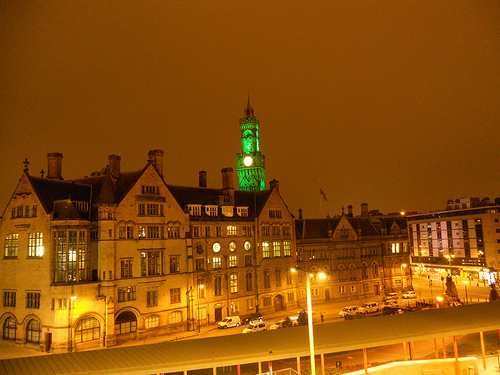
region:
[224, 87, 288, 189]
a clock tower lit up in green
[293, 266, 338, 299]
a street light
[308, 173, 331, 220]
a flag pole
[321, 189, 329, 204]
a flag hanging from the flag pole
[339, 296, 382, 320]
cars parked on the street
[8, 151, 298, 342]
a large building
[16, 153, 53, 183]
sculptures on top of the building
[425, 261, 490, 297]
traffic lights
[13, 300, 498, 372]
The roof of a covered walk way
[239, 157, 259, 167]
the clock on the clock tower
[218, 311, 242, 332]
a white van parked in front of a building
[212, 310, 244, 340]
a white van parked on side of raodway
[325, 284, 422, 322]
several vehicles parked on side of road way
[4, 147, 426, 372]
a large building with several windows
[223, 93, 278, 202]
a steeple on a building lit up in green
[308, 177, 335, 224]
a tall flag pole and flag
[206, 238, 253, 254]
three round windows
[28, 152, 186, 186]
three chimneys on a roof top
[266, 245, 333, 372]
a tall street light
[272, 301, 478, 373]
a covered walk way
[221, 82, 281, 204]
A green tower.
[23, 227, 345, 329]
A lot of lights are on.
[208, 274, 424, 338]
Cars are in the street.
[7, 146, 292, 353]
A large building.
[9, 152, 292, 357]
Lots of windows are in the building.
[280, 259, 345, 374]
A street light.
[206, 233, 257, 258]
Three round windows.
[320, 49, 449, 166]
The sky is overcast.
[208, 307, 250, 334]
A white van.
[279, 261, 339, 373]
The street lights are on.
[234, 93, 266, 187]
The tower is green.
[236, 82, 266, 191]
The tower sticks out.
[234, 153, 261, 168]
There is a clock on the tower.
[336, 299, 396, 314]
The cars are parked.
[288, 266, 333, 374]
The streetlight is on.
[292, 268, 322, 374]
The light shines bright.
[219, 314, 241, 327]
The van is white.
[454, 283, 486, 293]
The street is empty.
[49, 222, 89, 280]
The window is large.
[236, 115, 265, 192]
The light is green.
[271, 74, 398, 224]
fading sun in the skes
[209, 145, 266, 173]
bright white clock in building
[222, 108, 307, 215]
green top of building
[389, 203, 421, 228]
small white light at top fo building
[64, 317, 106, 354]
brown curved shape window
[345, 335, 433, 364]
brown panel on bridge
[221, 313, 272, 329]
white van parked in front of building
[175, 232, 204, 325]
tall black ladder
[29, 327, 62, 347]
tall black trash can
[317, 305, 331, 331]
man walking on the street